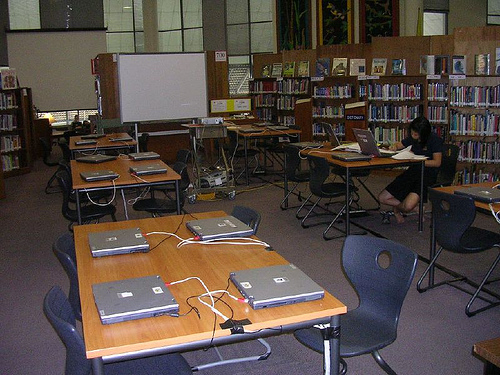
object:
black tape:
[220, 318, 254, 335]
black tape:
[322, 326, 344, 339]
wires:
[314, 322, 334, 373]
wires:
[183, 290, 200, 320]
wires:
[230, 236, 274, 249]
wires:
[84, 193, 102, 207]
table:
[426, 175, 500, 216]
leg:
[327, 316, 345, 373]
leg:
[85, 356, 105, 373]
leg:
[174, 179, 183, 214]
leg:
[418, 159, 424, 230]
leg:
[279, 146, 291, 208]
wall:
[273, 3, 415, 49]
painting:
[274, 0, 313, 54]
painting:
[316, 0, 355, 48]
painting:
[355, 0, 405, 45]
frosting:
[83, 180, 321, 344]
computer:
[88, 227, 149, 258]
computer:
[186, 215, 253, 242]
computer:
[230, 264, 326, 309]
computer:
[130, 163, 167, 176]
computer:
[90, 275, 180, 325]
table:
[61, 151, 189, 192]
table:
[63, 127, 138, 152]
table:
[222, 119, 299, 135]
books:
[400, 83, 404, 97]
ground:
[391, 148, 437, 173]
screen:
[0, 23, 112, 114]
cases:
[245, 33, 495, 192]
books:
[386, 82, 390, 101]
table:
[67, 207, 345, 358]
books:
[391, 127, 396, 144]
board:
[115, 50, 211, 125]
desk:
[72, 206, 346, 374]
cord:
[163, 275, 201, 289]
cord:
[207, 309, 227, 331]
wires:
[190, 141, 203, 166]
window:
[103, 0, 149, 53]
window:
[154, 0, 201, 48]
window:
[226, 0, 272, 51]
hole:
[378, 249, 392, 271]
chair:
[293, 234, 417, 375]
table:
[295, 140, 427, 168]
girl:
[378, 116, 444, 223]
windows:
[6, 0, 44, 32]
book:
[450, 54, 468, 80]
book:
[474, 51, 489, 76]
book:
[493, 47, 500, 75]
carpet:
[1, 152, 499, 374]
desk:
[224, 113, 301, 186]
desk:
[69, 151, 181, 225]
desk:
[66, 128, 137, 159]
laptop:
[354, 127, 400, 157]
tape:
[219, 317, 249, 335]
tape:
[320, 326, 343, 342]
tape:
[264, 246, 274, 252]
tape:
[259, 353, 272, 364]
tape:
[191, 364, 202, 373]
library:
[2, 4, 479, 374]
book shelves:
[247, 25, 500, 186]